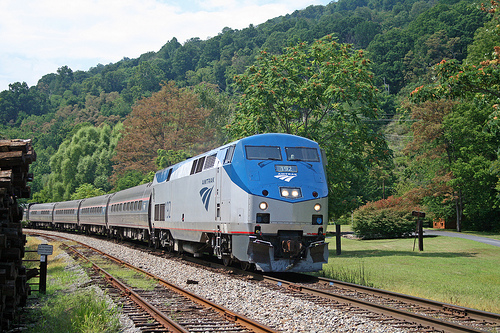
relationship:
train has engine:
[39, 122, 351, 290] [200, 242, 229, 259]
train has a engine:
[39, 122, 351, 290] [200, 242, 229, 259]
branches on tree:
[290, 105, 321, 131] [252, 41, 386, 129]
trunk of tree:
[333, 224, 351, 258] [252, 41, 386, 129]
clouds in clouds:
[44, 1, 151, 43] [44, 1, 151, 43]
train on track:
[39, 122, 351, 290] [285, 280, 380, 308]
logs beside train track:
[4, 133, 39, 329] [132, 279, 205, 322]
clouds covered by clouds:
[44, 1, 151, 43] [44, 1, 151, 43]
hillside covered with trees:
[149, 2, 466, 114] [302, 17, 438, 124]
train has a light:
[39, 122, 351, 290] [309, 201, 327, 216]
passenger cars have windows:
[41, 190, 157, 229] [55, 199, 147, 215]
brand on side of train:
[197, 175, 219, 187] [39, 122, 351, 290]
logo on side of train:
[196, 184, 220, 212] [39, 122, 351, 290]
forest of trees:
[79, 69, 179, 105] [302, 17, 438, 124]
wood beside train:
[1, 214, 23, 273] [39, 122, 351, 290]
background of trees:
[172, 36, 203, 45] [302, 17, 438, 124]